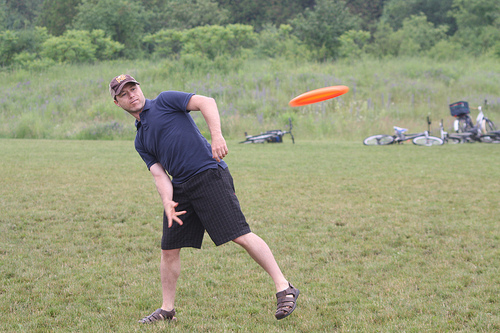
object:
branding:
[112, 73, 129, 81]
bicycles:
[239, 118, 299, 145]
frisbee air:
[283, 81, 355, 128]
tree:
[10, 24, 132, 80]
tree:
[134, 22, 313, 69]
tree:
[328, 13, 486, 70]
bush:
[4, 1, 499, 76]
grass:
[0, 136, 497, 331]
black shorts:
[159, 165, 253, 250]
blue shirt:
[132, 90, 227, 183]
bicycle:
[362, 112, 445, 148]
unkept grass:
[27, 56, 144, 138]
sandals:
[272, 283, 300, 322]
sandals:
[137, 300, 179, 326]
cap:
[108, 68, 143, 95]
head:
[108, 72, 147, 111]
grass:
[11, 58, 497, 123]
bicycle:
[450, 102, 477, 132]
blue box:
[448, 98, 471, 118]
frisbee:
[285, 79, 352, 109]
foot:
[133, 305, 183, 330]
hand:
[210, 133, 229, 163]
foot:
[275, 285, 298, 320]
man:
[106, 72, 300, 323]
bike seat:
[445, 99, 471, 116]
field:
[1, 136, 498, 331]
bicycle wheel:
[411, 135, 445, 146]